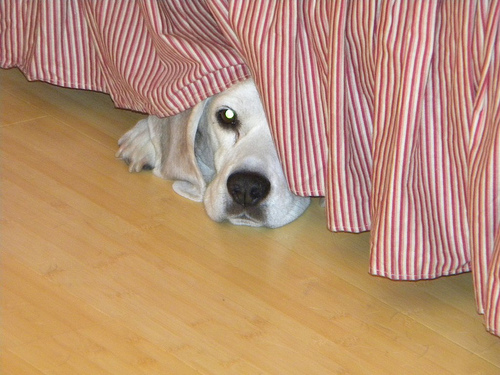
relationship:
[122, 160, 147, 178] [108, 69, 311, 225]
toenail on a dog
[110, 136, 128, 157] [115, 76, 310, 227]
toenail on a dog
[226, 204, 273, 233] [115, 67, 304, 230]
mouth of a dog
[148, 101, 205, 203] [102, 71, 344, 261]
ear of a dog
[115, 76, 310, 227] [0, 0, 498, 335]
dog peeping out from bed skirt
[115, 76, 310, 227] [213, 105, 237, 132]
dog has eye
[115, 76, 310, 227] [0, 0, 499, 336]
dog under bed skirt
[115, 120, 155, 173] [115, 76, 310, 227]
claws of a dog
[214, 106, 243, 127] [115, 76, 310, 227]
eye on dog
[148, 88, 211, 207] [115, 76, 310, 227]
ear on dog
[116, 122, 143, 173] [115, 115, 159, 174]
claws on paw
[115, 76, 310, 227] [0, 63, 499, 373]
dog laying on floor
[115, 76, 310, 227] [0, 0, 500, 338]
dog hiding under tablecloth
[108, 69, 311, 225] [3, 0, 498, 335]
dog peeking from under bed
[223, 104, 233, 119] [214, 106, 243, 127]
reflection in eye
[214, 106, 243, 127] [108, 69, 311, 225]
eye on dog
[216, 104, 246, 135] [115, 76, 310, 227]
eye on dog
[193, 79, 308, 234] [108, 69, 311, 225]
head on dog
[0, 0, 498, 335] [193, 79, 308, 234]
bed skirt on head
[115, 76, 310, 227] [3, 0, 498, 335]
dog laying under bed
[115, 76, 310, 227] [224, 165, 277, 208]
dog has nose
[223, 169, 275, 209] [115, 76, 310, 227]
nose on dog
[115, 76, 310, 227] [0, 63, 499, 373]
dog on floor